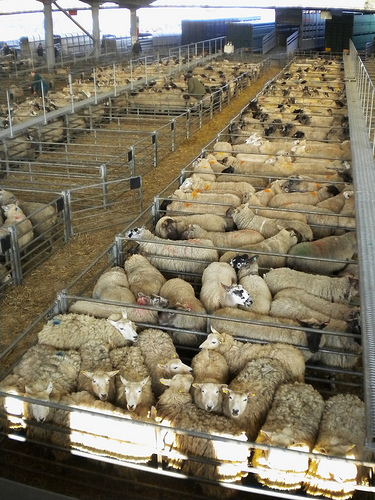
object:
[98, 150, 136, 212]
pens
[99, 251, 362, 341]
pen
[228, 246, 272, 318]
sheep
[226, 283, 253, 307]
faces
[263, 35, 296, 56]
ramp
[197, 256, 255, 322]
animals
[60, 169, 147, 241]
gate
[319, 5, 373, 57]
building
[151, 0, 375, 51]
loading dock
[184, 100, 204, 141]
animal pens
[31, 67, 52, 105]
person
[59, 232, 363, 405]
cages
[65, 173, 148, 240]
fence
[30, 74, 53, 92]
jacket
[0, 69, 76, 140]
pen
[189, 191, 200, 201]
marking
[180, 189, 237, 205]
back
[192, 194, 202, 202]
tags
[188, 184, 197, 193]
ears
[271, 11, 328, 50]
truck